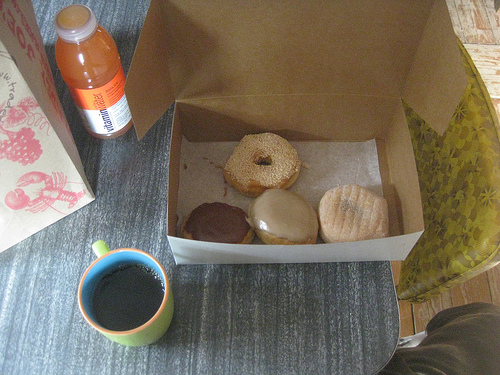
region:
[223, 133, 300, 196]
a sprinkled doughnut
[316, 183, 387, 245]
a sugared jelly doughnut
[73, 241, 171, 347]
a blue and green mug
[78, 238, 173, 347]
a mug of coffee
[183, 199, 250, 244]
a chocolate frosted creme filled doughnut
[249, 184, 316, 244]
a frosted doughnut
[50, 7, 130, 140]
a sports drink bottle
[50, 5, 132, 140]
an orange drink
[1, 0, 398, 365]
a grey patterned table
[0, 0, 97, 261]
a paper grocery bag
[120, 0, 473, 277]
a box with four donuts inside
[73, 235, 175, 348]
a cup of black coffee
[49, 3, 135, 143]
a bottle of orange vitamin water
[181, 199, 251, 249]
a chocolate covered donut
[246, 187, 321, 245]
a vanilla covered donut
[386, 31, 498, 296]
a chair back with a yellow design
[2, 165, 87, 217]
bag with a lobster design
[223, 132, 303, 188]
donut with coconut sprinkles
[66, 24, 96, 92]
light reflecting off the vitamin water bottle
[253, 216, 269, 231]
light reflecting off the vanilla donut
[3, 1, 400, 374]
Gray table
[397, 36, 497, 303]
Chair under the table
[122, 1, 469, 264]
Paper box on the table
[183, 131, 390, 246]
Doughnuts in the paper box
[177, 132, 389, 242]
A piece of white paper under the doughnuts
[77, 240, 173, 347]
Mug on the table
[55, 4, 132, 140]
A bottle of drink on the table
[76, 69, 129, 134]
Label on the drink bottle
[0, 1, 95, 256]
Paper bag on the table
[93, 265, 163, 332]
Drink in the mug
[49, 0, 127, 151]
orange drink next to box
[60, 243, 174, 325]
coffee in the mug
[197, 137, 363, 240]
four donuts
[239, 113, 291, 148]
donuts in a box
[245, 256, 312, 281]
donut box is on the table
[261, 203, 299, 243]
glazed donut in the box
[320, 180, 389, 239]
jelly donut in the box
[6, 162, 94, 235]
picture of a lobster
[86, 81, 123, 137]
vitaminwater is the name of the drink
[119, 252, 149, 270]
inside the mug is aqua blue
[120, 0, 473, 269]
The donuts are in a box.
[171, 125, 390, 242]
White tissue paper beneath the donuts.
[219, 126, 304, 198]
The donut has a hole in the middle.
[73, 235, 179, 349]
The cup is blue inside.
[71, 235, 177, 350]
The cup has a handle.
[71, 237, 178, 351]
The rim of the cup is white.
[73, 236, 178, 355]
The cup is green outside.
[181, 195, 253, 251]
The donut has icing on top.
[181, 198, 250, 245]
The icing is brown.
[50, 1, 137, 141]
The bottle is full.